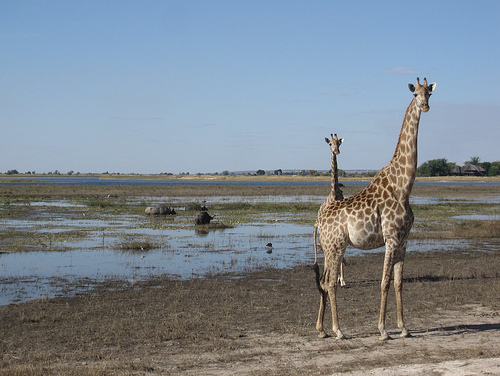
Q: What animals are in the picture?
A: Giraffes.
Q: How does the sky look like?
A: Clear and blue.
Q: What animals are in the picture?
A: Brown and tan giraffes.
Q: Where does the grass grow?
A: On the water.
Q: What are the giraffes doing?
A: The giraffes are looking forward.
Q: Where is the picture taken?
A: Africa.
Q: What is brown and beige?
A: Giraffe.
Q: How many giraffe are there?
A: Two.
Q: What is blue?
A: Sky.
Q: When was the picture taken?
A: Daytime.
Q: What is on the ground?
A: Water.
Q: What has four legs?
A: One giraffe.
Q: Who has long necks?
A: The giraffe.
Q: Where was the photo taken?
A: Near giraffes.